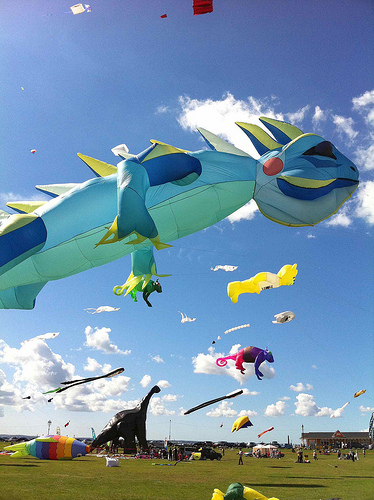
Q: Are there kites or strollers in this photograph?
A: Yes, there is a kite.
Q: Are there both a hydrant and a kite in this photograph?
A: No, there is a kite but no fire hydrants.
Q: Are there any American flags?
A: No, there are no American flags.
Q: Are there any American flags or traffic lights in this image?
A: No, there are no American flags or traffic lights.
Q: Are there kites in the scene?
A: Yes, there is a kite.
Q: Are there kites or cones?
A: Yes, there is a kite.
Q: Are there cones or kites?
A: Yes, there is a kite.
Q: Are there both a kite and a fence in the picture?
A: No, there is a kite but no fences.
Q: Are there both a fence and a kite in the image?
A: No, there is a kite but no fences.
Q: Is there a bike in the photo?
A: No, there are no bikes.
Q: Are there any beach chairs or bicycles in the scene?
A: No, there are no bicycles or beach chairs.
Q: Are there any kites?
A: Yes, there is a kite.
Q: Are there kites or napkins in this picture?
A: Yes, there is a kite.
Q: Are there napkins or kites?
A: Yes, there is a kite.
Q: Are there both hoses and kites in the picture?
A: No, there is a kite but no hoses.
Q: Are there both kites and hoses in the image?
A: No, there is a kite but no hoses.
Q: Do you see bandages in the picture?
A: No, there are no bandages.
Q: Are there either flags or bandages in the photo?
A: No, there are no bandages or flags.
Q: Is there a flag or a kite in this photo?
A: Yes, there is a kite.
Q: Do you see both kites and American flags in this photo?
A: No, there is a kite but no American flags.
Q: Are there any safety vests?
A: No, there are no safety vests.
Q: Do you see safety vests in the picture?
A: No, there are no safety vests.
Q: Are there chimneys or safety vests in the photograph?
A: No, there are no safety vests or chimneys.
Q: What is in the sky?
A: The kite is in the sky.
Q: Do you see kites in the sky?
A: Yes, there is a kite in the sky.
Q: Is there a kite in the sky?
A: Yes, there is a kite in the sky.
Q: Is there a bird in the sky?
A: No, there is a kite in the sky.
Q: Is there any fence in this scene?
A: No, there are no fences.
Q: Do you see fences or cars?
A: No, there are no fences or cars.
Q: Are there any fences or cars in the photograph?
A: No, there are no fences or cars.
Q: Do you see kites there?
A: Yes, there is a kite.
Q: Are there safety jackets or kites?
A: Yes, there is a kite.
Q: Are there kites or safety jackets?
A: Yes, there is a kite.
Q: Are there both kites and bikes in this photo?
A: No, there is a kite but no bikes.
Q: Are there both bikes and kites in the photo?
A: No, there is a kite but no bikes.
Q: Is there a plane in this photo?
A: No, there are no airplanes.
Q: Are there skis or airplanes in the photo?
A: No, there are no airplanes or skis.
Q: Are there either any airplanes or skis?
A: No, there are no airplanes or skis.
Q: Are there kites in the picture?
A: Yes, there is a kite.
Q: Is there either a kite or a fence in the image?
A: Yes, there is a kite.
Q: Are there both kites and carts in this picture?
A: No, there is a kite but no carts.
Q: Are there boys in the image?
A: No, there are no boys.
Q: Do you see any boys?
A: No, there are no boys.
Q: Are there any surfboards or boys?
A: No, there are no boys or surfboards.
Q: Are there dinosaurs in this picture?
A: Yes, there is a dinosaur.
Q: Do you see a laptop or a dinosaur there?
A: Yes, there is a dinosaur.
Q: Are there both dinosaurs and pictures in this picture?
A: No, there is a dinosaur but no pictures.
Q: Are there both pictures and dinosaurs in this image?
A: No, there is a dinosaur but no pictures.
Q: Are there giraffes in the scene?
A: No, there are no giraffes.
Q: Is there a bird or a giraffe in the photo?
A: No, there are no giraffes or birds.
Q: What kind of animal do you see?
A: The animal is a dinosaur.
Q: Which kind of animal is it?
A: The animal is a dinosaur.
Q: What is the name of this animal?
A: This is a dinosaur.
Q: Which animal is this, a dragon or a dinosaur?
A: This is a dinosaur.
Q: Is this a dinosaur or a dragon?
A: This is a dinosaur.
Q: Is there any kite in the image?
A: Yes, there is a kite.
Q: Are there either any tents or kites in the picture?
A: Yes, there is a kite.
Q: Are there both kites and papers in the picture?
A: No, there is a kite but no papers.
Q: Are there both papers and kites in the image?
A: No, there is a kite but no papers.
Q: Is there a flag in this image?
A: No, there are no flags.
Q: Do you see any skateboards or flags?
A: No, there are no flags or skateboards.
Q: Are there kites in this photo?
A: Yes, there is a kite.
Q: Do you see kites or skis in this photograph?
A: Yes, there is a kite.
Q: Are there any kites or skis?
A: Yes, there is a kite.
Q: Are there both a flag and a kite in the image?
A: No, there is a kite but no flags.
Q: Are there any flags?
A: No, there are no flags.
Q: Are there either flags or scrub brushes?
A: No, there are no flags or scrub brushes.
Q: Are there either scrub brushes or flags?
A: No, there are no flags or scrub brushes.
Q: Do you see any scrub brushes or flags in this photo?
A: No, there are no flags or scrub brushes.